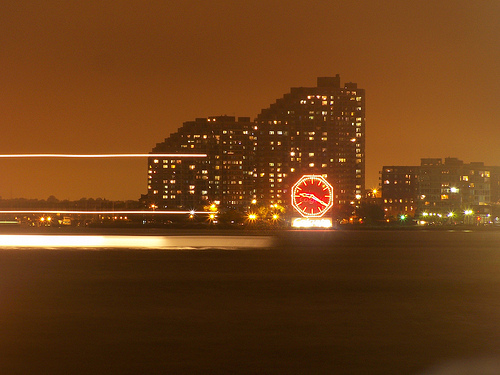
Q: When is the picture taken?
A: 9:20.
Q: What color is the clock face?
A: Red.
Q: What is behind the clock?
A: Building.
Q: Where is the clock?
A: Across the water.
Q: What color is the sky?
A: Brown.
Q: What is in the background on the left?
A: Trees.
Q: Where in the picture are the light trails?
A: On the left.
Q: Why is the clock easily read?
A: It's illuminated.